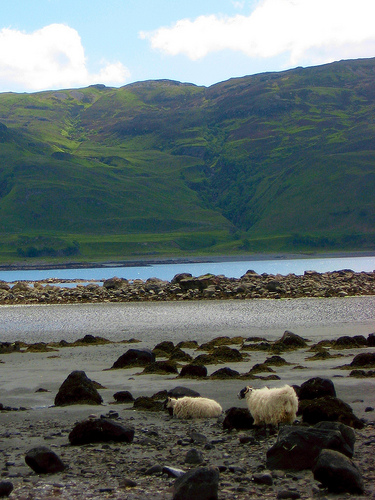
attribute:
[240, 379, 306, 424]
animal — white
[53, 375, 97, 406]
rock — dark, large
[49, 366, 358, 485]
rocks — large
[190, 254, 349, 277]
water — blue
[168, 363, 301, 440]
sheep — white, furry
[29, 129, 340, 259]
hills — green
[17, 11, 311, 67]
sky — blue, cloudy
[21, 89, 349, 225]
mountain — sun-lit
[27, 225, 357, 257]
trees — green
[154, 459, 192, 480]
bottle — black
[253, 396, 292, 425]
wool — white